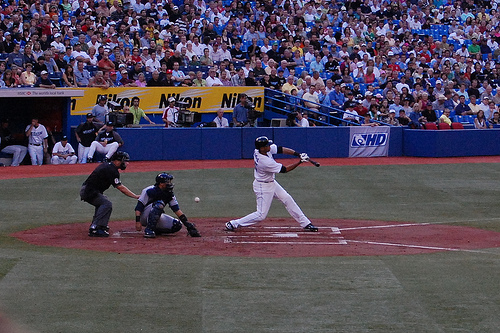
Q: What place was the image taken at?
A: It was taken at the stadium.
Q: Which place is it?
A: It is a stadium.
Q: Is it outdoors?
A: Yes, it is outdoors.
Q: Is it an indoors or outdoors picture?
A: It is outdoors.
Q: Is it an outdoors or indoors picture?
A: It is outdoors.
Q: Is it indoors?
A: No, it is outdoors.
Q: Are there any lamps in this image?
A: No, there are no lamps.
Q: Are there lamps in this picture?
A: No, there are no lamps.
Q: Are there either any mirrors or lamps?
A: No, there are no lamps or mirrors.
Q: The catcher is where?
A: The catcher is in the field.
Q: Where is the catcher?
A: The catcher is in the field.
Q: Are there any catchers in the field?
A: Yes, there is a catcher in the field.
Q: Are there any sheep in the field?
A: No, there is a catcher in the field.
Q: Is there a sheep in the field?
A: No, there is a catcher in the field.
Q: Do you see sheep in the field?
A: No, there is a catcher in the field.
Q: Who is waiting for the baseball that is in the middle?
A: The catcher is waiting for the baseball.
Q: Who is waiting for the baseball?
A: The catcher is waiting for the baseball.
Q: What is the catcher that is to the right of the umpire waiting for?
A: The catcher is waiting for the baseball.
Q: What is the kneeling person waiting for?
A: The catcher is waiting for the baseball.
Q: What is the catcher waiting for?
A: The catcher is waiting for the baseball.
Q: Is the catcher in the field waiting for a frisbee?
A: No, the catcher is waiting for the baseball.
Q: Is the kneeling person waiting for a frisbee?
A: No, the catcher is waiting for the baseball.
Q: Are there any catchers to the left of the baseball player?
A: Yes, there is a catcher to the left of the player.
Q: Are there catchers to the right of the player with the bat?
A: No, the catcher is to the left of the player.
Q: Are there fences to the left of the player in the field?
A: No, there is a catcher to the left of the player.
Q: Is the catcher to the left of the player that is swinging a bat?
A: Yes, the catcher is to the left of the player.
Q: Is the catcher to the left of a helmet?
A: No, the catcher is to the left of the player.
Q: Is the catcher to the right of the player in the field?
A: No, the catcher is to the left of the player.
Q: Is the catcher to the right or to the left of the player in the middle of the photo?
A: The catcher is to the left of the player.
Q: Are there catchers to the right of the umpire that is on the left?
A: Yes, there is a catcher to the right of the umpire.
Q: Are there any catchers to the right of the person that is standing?
A: Yes, there is a catcher to the right of the umpire.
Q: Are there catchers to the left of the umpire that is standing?
A: No, the catcher is to the right of the umpire.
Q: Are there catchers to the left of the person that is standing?
A: No, the catcher is to the right of the umpire.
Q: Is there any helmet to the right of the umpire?
A: No, there is a catcher to the right of the umpire.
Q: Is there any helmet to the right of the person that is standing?
A: No, there is a catcher to the right of the umpire.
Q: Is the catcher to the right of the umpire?
A: Yes, the catcher is to the right of the umpire.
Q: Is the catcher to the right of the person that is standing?
A: Yes, the catcher is to the right of the umpire.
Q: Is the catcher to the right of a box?
A: No, the catcher is to the right of the umpire.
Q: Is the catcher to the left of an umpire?
A: No, the catcher is to the right of an umpire.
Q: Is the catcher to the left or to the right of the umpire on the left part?
A: The catcher is to the right of the umpire.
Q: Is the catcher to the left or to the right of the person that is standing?
A: The catcher is to the right of the umpire.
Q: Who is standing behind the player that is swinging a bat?
A: The catcher is standing behind the player.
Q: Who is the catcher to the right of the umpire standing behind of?
A: The catcher is standing behind the player.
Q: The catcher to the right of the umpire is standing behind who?
A: The catcher is standing behind the player.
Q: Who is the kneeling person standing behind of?
A: The catcher is standing behind the player.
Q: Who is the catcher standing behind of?
A: The catcher is standing behind the player.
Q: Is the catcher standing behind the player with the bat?
A: Yes, the catcher is standing behind the player.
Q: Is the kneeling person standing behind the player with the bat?
A: Yes, the catcher is standing behind the player.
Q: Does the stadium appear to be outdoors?
A: Yes, the stadium is outdoors.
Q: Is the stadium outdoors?
A: Yes, the stadium is outdoors.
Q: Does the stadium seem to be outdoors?
A: Yes, the stadium is outdoors.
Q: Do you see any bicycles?
A: No, there are no bicycles.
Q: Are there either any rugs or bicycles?
A: No, there are no bicycles or rugs.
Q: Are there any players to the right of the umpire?
A: Yes, there is a player to the right of the umpire.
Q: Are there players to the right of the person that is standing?
A: Yes, there is a player to the right of the umpire.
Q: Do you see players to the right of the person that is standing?
A: Yes, there is a player to the right of the umpire.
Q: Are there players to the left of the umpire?
A: No, the player is to the right of the umpire.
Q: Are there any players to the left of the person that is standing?
A: No, the player is to the right of the umpire.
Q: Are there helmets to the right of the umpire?
A: No, there is a player to the right of the umpire.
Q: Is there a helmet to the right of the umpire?
A: No, there is a player to the right of the umpire.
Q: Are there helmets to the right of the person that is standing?
A: No, there is a player to the right of the umpire.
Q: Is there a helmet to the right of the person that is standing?
A: No, there is a player to the right of the umpire.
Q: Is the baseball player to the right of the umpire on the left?
A: Yes, the player is to the right of the umpire.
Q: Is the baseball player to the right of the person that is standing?
A: Yes, the player is to the right of the umpire.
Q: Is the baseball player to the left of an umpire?
A: No, the player is to the right of an umpire.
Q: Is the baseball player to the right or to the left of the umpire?
A: The player is to the right of the umpire.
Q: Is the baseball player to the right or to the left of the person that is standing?
A: The player is to the right of the umpire.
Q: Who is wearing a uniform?
A: The player is wearing a uniform.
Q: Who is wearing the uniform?
A: The player is wearing a uniform.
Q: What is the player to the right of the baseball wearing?
A: The player is wearing a uniform.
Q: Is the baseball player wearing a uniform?
A: Yes, the player is wearing a uniform.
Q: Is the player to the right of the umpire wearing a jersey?
A: No, the player is wearing a uniform.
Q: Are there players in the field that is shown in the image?
A: Yes, there is a player in the field.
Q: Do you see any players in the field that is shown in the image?
A: Yes, there is a player in the field.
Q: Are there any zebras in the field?
A: No, there is a player in the field.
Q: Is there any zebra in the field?
A: No, there is a player in the field.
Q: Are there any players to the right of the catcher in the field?
A: Yes, there is a player to the right of the catcher.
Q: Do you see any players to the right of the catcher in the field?
A: Yes, there is a player to the right of the catcher.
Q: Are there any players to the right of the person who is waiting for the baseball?
A: Yes, there is a player to the right of the catcher.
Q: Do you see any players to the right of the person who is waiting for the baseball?
A: Yes, there is a player to the right of the catcher.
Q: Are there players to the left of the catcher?
A: No, the player is to the right of the catcher.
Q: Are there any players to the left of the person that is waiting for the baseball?
A: No, the player is to the right of the catcher.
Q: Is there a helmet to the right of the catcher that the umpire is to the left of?
A: No, there is a player to the right of the catcher.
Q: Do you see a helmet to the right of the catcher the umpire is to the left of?
A: No, there is a player to the right of the catcher.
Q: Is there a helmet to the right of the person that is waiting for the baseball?
A: No, there is a player to the right of the catcher.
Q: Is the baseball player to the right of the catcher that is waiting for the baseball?
A: Yes, the player is to the right of the catcher.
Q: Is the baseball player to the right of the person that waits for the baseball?
A: Yes, the player is to the right of the catcher.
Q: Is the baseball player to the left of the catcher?
A: No, the player is to the right of the catcher.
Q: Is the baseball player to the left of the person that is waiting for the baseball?
A: No, the player is to the right of the catcher.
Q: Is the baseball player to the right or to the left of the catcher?
A: The player is to the right of the catcher.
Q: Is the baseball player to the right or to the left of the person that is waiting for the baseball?
A: The player is to the right of the catcher.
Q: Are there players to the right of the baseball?
A: Yes, there is a player to the right of the baseball.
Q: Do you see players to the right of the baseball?
A: Yes, there is a player to the right of the baseball.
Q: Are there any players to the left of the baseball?
A: No, the player is to the right of the baseball.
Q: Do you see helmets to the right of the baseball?
A: No, there is a player to the right of the baseball.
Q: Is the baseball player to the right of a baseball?
A: Yes, the player is to the right of a baseball.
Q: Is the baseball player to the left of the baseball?
A: No, the player is to the right of the baseball.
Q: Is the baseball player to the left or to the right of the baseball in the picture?
A: The player is to the right of the baseball.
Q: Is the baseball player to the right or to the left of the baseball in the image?
A: The player is to the right of the baseball.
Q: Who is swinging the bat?
A: The player is swinging the bat.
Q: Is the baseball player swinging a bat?
A: Yes, the player is swinging a bat.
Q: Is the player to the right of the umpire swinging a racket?
A: No, the player is swinging a bat.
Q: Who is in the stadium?
A: The spectators are in the stadium.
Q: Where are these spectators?
A: The spectators are in the stadium.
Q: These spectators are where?
A: The spectators are in the stadium.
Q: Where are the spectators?
A: The spectators are in the stadium.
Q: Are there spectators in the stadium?
A: Yes, there are spectators in the stadium.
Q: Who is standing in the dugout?
A: The player is standing in the dugout.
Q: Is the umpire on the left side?
A: Yes, the umpire is on the left of the image.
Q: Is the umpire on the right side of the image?
A: No, the umpire is on the left of the image.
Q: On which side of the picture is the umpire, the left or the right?
A: The umpire is on the left of the image.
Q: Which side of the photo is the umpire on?
A: The umpire is on the left of the image.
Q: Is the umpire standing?
A: Yes, the umpire is standing.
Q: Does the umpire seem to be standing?
A: Yes, the umpire is standing.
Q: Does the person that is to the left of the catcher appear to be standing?
A: Yes, the umpire is standing.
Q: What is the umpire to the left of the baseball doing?
A: The umpire is standing.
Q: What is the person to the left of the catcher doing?
A: The umpire is standing.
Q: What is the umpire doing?
A: The umpire is standing.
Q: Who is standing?
A: The umpire is standing.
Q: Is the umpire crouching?
A: No, the umpire is standing.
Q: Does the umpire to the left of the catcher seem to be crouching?
A: No, the umpire is standing.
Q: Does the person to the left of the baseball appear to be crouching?
A: No, the umpire is standing.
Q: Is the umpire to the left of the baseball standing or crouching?
A: The umpire is standing.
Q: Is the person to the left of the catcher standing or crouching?
A: The umpire is standing.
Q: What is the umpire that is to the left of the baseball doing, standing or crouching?
A: The umpire is standing.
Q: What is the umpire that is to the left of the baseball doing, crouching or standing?
A: The umpire is standing.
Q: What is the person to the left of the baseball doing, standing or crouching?
A: The umpire is standing.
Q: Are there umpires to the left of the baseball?
A: Yes, there is an umpire to the left of the baseball.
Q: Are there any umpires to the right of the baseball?
A: No, the umpire is to the left of the baseball.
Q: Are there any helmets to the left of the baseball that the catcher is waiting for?
A: No, there is an umpire to the left of the baseball.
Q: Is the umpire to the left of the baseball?
A: Yes, the umpire is to the left of the baseball.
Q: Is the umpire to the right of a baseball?
A: No, the umpire is to the left of a baseball.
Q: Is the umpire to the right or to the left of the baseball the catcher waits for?
A: The umpire is to the left of the baseball.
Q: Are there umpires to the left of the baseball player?
A: Yes, there is an umpire to the left of the player.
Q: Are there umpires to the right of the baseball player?
A: No, the umpire is to the left of the player.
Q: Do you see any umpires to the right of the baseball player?
A: No, the umpire is to the left of the player.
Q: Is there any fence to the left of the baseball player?
A: No, there is an umpire to the left of the player.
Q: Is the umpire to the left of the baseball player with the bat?
A: Yes, the umpire is to the left of the player.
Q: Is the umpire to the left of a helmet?
A: No, the umpire is to the left of the player.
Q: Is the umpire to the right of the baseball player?
A: No, the umpire is to the left of the player.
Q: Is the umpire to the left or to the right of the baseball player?
A: The umpire is to the left of the player.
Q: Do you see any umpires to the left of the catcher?
A: Yes, there is an umpire to the left of the catcher.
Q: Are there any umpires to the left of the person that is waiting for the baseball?
A: Yes, there is an umpire to the left of the catcher.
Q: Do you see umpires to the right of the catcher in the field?
A: No, the umpire is to the left of the catcher.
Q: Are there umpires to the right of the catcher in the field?
A: No, the umpire is to the left of the catcher.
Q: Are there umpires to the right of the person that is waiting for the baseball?
A: No, the umpire is to the left of the catcher.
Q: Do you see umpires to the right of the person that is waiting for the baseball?
A: No, the umpire is to the left of the catcher.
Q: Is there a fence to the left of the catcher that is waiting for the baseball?
A: No, there is an umpire to the left of the catcher.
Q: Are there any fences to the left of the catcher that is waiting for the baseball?
A: No, there is an umpire to the left of the catcher.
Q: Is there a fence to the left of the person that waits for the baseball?
A: No, there is an umpire to the left of the catcher.